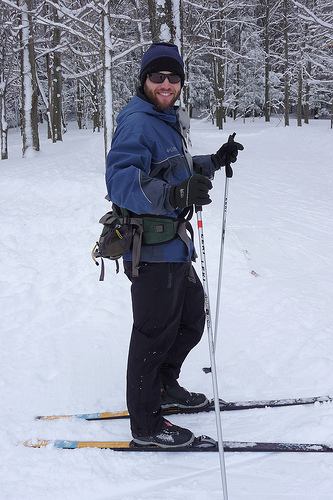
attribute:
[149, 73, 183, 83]
sunglasses — dark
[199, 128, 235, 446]
skis — long, yellow, black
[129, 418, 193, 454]
sneaker — black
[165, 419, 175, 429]
lace — red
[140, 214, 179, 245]
fanny pack — green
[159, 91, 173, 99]
grin — toothy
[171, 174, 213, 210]
winter glove — warm, black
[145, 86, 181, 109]
beard — bushy, brown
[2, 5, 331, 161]
trees — snow-covered, leafless, covered in snow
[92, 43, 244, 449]
man — smiling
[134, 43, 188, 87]
ski cap — black, blue, knit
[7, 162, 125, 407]
snow — on ground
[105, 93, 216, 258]
jacket — blue, grey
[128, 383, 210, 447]
man's feet — black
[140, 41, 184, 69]
stocking cap — blue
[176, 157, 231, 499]
poles — in man's hands, silver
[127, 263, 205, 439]
ski pants — black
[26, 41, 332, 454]
skier — bearded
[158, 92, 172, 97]
smile — toothy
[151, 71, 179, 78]
frames — black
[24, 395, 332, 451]
skis — black, blue, tan, covered in snow